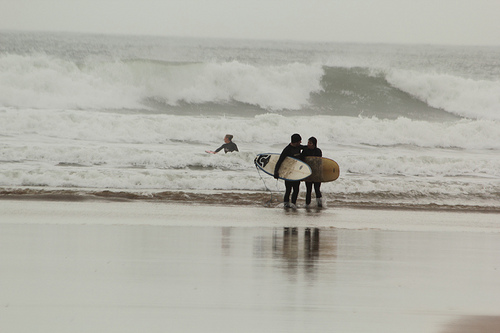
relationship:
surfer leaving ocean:
[273, 130, 306, 210] [1, 30, 499, 235]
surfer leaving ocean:
[299, 134, 328, 209] [1, 30, 499, 235]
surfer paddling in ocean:
[205, 131, 238, 156] [1, 30, 499, 235]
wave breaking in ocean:
[2, 51, 499, 122] [1, 30, 499, 235]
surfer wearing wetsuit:
[273, 130, 306, 210] [273, 142, 305, 204]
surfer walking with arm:
[273, 130, 306, 210] [299, 141, 309, 151]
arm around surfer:
[299, 141, 309, 151] [299, 134, 328, 209]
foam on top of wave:
[2, 52, 499, 116] [2, 51, 499, 122]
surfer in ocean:
[273, 130, 306, 210] [1, 30, 499, 235]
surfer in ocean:
[299, 134, 328, 209] [1, 30, 499, 235]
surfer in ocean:
[205, 131, 238, 156] [1, 30, 499, 235]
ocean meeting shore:
[1, 30, 499, 235] [1, 196, 499, 331]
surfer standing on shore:
[273, 130, 306, 210] [1, 196, 499, 331]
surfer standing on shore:
[299, 134, 328, 209] [1, 196, 499, 331]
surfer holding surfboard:
[273, 130, 306, 210] [249, 152, 311, 181]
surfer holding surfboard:
[299, 134, 328, 209] [299, 152, 340, 183]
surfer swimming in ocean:
[205, 131, 238, 156] [1, 30, 499, 235]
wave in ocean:
[2, 51, 499, 122] [1, 30, 499, 235]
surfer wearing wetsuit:
[299, 134, 328, 209] [300, 145, 323, 205]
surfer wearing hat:
[273, 130, 306, 210] [292, 133, 301, 144]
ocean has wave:
[1, 30, 499, 235] [2, 51, 499, 122]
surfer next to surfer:
[273, 130, 306, 210] [299, 134, 328, 209]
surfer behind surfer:
[205, 131, 238, 156] [273, 130, 306, 210]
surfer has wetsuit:
[273, 130, 306, 210] [273, 142, 305, 204]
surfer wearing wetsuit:
[205, 131, 238, 156] [217, 140, 241, 156]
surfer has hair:
[205, 131, 238, 156] [224, 132, 237, 139]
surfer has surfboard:
[273, 130, 306, 210] [249, 152, 311, 181]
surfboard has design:
[249, 152, 311, 181] [255, 154, 273, 170]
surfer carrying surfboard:
[273, 130, 306, 210] [249, 152, 311, 181]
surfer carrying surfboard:
[299, 134, 328, 209] [299, 152, 340, 183]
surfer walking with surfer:
[273, 130, 306, 210] [299, 134, 328, 209]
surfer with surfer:
[273, 130, 306, 210] [299, 134, 328, 209]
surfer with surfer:
[205, 131, 238, 156] [273, 130, 306, 210]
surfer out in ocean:
[205, 131, 238, 156] [1, 30, 499, 235]